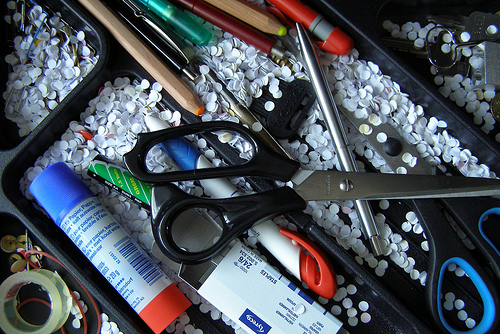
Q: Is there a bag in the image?
A: No, there are no bags.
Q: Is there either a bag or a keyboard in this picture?
A: No, there are no bags or keyboards.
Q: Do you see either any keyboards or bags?
A: No, there are no bags or keyboards.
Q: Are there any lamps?
A: No, there are no lamps.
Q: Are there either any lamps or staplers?
A: No, there are no lamps or staplers.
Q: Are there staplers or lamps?
A: No, there are no lamps or staplers.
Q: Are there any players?
A: No, there are no players.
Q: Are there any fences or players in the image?
A: No, there are no players or fences.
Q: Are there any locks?
A: No, there are no locks.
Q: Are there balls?
A: No, there are no balls.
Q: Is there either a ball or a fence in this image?
A: No, there are no balls or fences.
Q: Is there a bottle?
A: No, there are no bottles.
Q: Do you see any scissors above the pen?
A: Yes, there are scissors above the pen.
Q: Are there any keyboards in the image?
A: No, there are no keyboards.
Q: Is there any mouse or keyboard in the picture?
A: No, there are no keyboards or computer mice.